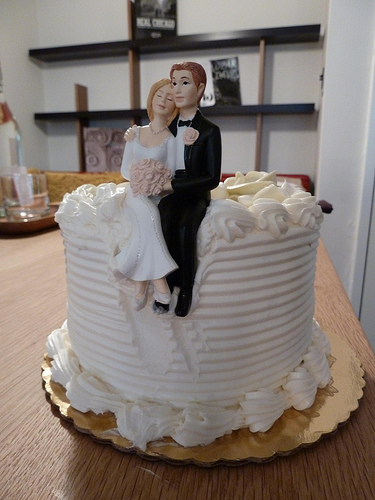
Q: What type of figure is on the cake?
A: A couple.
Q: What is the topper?
A: A man and woman.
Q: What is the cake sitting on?
A: A plate.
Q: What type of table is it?
A: Wood.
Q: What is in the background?
A: Walls.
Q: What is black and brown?
A: The bookcase.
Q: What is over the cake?
A: Frosting.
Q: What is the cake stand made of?
A: Cardboard.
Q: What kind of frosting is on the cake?
A: White frosting.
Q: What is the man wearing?
A: A tuxedo.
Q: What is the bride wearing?
A: A wedding dress.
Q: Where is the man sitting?
A: On the cake.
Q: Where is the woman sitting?
A: On the cake.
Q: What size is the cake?
A: Small.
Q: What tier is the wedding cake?
A: The top tier.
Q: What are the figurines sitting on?
A: Wedding cake.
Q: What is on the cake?
A: Bride and groom.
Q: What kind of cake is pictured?
A: Wedding cake.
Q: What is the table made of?
A: Wood.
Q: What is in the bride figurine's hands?
A: Flowers.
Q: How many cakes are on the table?
A: One.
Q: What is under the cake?
A: A cake board.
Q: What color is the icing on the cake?
A: White.